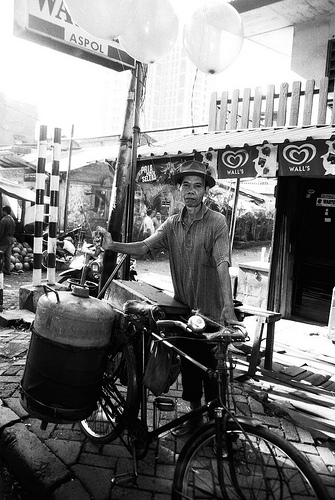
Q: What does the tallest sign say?
A: Aspol.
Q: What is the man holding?
A: Bicycle.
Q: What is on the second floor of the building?
A: Fence.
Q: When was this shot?
A: Daytime.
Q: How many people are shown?
A: 1.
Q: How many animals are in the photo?
A: 0.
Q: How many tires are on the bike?
A: 2.